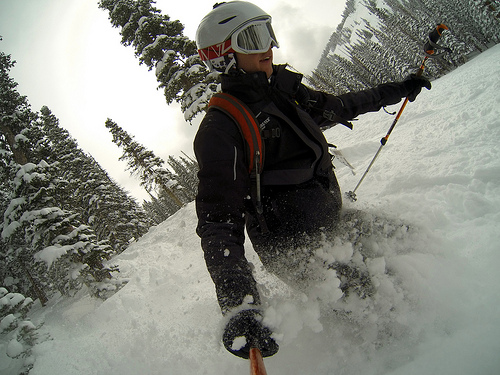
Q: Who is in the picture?
A: A skier.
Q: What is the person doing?
A: Skiing.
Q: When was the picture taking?
A: During the day.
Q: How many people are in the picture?
A: One.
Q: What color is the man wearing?
A: Black.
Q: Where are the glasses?
A: On the man's face.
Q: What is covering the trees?
A: Snow.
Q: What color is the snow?
A: White.